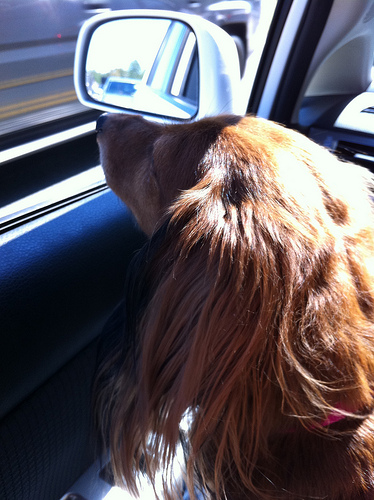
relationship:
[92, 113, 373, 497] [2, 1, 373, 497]
dog in car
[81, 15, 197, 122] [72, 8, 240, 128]
reflection in mirror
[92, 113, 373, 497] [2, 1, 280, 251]
dog looking outside window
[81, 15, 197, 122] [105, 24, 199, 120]
reflection on door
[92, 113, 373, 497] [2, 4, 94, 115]
dog looking outside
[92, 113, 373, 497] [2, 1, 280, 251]
dog looking through window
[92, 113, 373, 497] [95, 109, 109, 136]
dog has nose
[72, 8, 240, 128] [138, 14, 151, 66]
mirror has part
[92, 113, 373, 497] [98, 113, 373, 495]
dog has hair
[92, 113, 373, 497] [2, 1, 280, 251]
dog looking out of window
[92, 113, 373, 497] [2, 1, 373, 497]
dog staring outside of car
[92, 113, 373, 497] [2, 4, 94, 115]
dog staring outside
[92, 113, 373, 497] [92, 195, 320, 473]
dog has ear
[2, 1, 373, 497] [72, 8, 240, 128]
car has mirror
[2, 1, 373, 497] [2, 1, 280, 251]
car has window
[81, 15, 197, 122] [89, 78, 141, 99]
reflection has car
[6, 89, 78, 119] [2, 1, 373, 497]
pole outside car